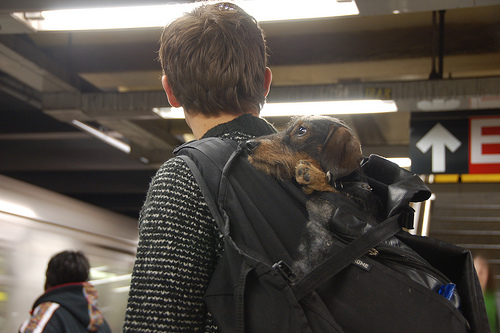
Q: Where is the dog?
A: In the backpack.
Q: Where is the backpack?
A: On the man's back.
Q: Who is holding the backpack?
A: The man in the sweater.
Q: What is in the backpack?
A: A dog.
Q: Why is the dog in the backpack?
A: To stay with its owner.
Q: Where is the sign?
A: Behind the dog.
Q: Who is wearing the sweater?
A: The front man.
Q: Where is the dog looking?
A: Forward.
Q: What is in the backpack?
A: Dog.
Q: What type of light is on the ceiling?
A: Fluorescent.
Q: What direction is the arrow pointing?
A: Up.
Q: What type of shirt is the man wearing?
A: Sweater.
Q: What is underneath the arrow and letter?
A: Stairs.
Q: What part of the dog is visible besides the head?
A: Paw.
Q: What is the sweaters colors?
A: Black and white.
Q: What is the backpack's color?
A: Black.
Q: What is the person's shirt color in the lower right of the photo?
A: Green.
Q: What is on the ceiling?
A: Lights.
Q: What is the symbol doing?
A: Pointing.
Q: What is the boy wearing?
A: Sweater..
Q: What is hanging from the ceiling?
A: Sign.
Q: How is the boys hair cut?
A: Short.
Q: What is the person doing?
A: Waiting.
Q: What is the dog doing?
A: Looking.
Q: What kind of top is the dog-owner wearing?
A: A sweater.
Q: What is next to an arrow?
A: The letter B.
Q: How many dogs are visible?
A: One.